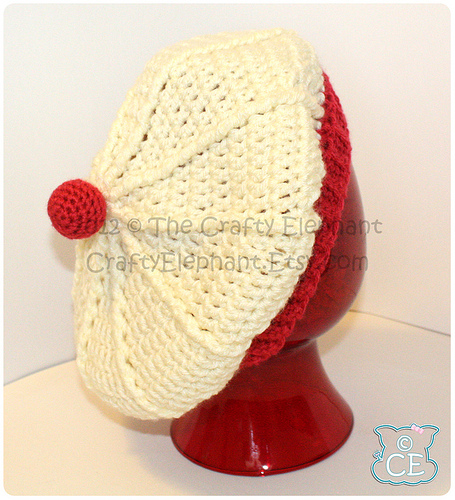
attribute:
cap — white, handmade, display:
[32, 28, 335, 416]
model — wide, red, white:
[183, 124, 395, 440]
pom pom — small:
[38, 177, 117, 237]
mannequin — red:
[173, 159, 389, 464]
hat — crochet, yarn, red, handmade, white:
[45, 26, 366, 427]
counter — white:
[6, 293, 449, 498]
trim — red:
[236, 56, 361, 370]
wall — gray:
[8, 9, 445, 496]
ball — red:
[42, 176, 120, 236]